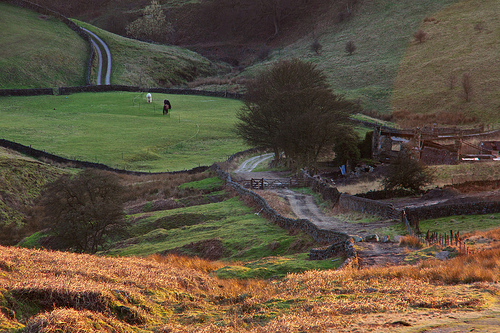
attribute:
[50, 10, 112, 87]
road — rough, dirty, tracked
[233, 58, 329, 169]
tree — towering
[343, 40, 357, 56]
tree — small, growing, short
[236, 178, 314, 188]
fence — wide, black, wooden, tall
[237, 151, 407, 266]
road — bumpy, blocked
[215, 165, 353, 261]
fence — low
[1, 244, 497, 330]
grass — brown, golden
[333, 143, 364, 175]
tree — small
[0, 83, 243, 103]
fence — stone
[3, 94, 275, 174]
field — green, grassy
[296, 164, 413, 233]
wall — short, stone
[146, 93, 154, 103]
horse — white, grazing, fenced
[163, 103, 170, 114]
horse — grazing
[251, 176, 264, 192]
gate — wooden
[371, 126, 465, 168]
building — ruined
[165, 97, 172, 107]
horse — dark